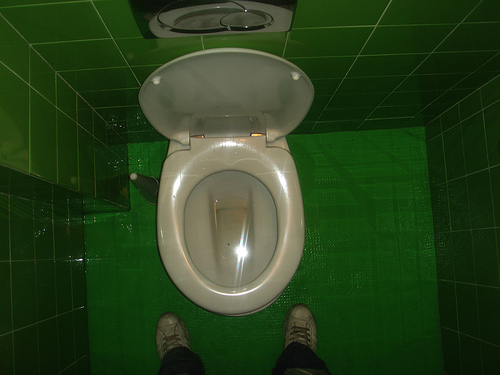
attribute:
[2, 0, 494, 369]
tiled — green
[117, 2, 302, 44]
paper dispenser — toilet paper dispenser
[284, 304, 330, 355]
sneaker — white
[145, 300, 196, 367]
sneaker — white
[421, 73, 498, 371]
tile — Bright green, tile wall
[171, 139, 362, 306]
bowl — toilet bowl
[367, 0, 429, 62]
tile — green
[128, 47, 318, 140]
toilet lid — is up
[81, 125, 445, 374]
floor tiles — bright green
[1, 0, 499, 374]
walls — green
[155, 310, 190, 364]
shoe — white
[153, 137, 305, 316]
seat — is down, toilet seat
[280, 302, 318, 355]
shoe — white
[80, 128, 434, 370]
tile — green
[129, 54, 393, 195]
lid — white, sitting up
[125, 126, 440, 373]
floor — bright green, tiled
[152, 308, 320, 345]
shoes — white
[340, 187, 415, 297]
item — cone shaped